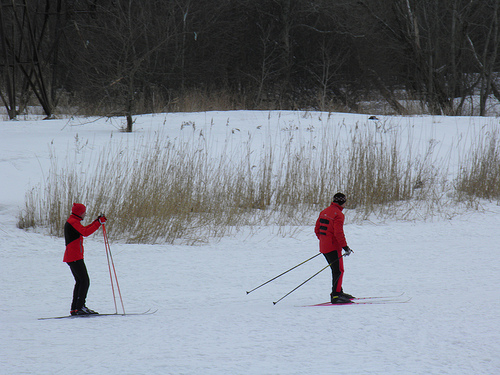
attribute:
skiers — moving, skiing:
[27, 185, 413, 321]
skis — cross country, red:
[33, 308, 164, 329]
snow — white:
[207, 305, 486, 374]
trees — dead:
[59, 4, 480, 107]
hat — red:
[68, 199, 87, 220]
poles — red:
[93, 211, 125, 320]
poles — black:
[243, 247, 354, 307]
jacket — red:
[309, 201, 358, 257]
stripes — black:
[315, 217, 334, 238]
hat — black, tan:
[329, 190, 351, 207]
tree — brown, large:
[97, 14, 157, 117]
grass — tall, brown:
[103, 129, 399, 234]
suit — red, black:
[55, 202, 92, 312]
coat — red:
[57, 210, 108, 267]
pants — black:
[64, 259, 98, 314]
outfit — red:
[310, 197, 348, 303]